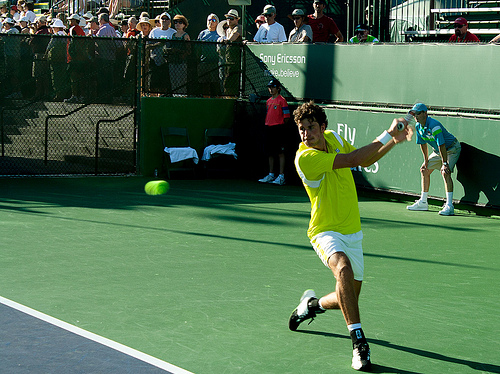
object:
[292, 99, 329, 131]
hair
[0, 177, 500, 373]
hardcourt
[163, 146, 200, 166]
towels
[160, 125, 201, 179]
chairs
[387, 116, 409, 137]
hand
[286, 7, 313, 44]
fans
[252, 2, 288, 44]
fans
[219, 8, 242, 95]
fans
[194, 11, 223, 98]
fans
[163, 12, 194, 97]
fans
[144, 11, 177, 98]
fans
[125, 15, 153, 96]
fans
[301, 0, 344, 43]
fans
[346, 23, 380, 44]
fans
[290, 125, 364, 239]
man's shirt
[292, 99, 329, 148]
head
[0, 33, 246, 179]
fence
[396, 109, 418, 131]
racket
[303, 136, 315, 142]
mouth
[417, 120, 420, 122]
mouth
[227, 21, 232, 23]
mouth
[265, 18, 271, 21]
mouth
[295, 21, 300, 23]
mouth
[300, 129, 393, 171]
arm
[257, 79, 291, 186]
ball boy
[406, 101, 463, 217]
ball boy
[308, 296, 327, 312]
socks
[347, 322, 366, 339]
socks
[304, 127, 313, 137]
nose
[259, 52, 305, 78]
advertisement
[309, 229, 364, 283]
man's shorts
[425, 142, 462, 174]
man's shorts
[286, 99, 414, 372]
man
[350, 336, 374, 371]
shoe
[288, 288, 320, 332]
shoe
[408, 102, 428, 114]
blue hat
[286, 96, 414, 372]
athlete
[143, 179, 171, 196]
ball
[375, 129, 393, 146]
wrist band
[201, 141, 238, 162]
towels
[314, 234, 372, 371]
leg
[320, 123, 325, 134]
ear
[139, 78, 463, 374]
tennis match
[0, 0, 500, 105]
crowd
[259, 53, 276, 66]
sony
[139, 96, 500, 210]
wall